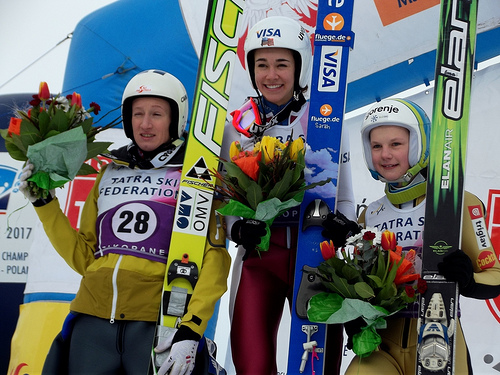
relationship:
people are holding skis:
[32, 8, 499, 373] [147, 0, 249, 372]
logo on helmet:
[252, 27, 282, 39] [228, 13, 314, 95]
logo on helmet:
[361, 105, 402, 120] [114, 65, 191, 142]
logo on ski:
[314, 42, 341, 94] [284, 0, 355, 371]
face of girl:
[371, 126, 405, 178] [343, 98, 500, 375]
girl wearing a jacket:
[343, 98, 500, 375] [75, 147, 223, 305]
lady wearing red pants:
[218, 14, 355, 372] [229, 220, 342, 371]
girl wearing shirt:
[356, 102, 441, 219] [366, 202, 423, 244]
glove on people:
[146, 321, 201, 366] [16, 68, 231, 375]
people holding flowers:
[32, 8, 499, 373] [1, 66, 433, 356]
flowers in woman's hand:
[3, 66, 137, 277] [11, 158, 52, 201]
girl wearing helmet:
[343, 98, 500, 375] [359, 98, 430, 187]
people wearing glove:
[16, 68, 231, 375] [153, 330, 203, 372]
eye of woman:
[134, 107, 145, 117] [11, 67, 230, 373]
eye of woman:
[148, 109, 161, 116] [11, 67, 230, 373]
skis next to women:
[151, 3, 480, 373] [356, 100, 450, 357]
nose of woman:
[263, 60, 280, 82] [217, 13, 359, 373]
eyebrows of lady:
[251, 55, 296, 65] [217, 16, 358, 375]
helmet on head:
[117, 64, 198, 140] [127, 98, 177, 152]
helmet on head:
[243, 14, 316, 94] [248, 47, 300, 103]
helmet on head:
[361, 95, 431, 175] [363, 123, 411, 179]